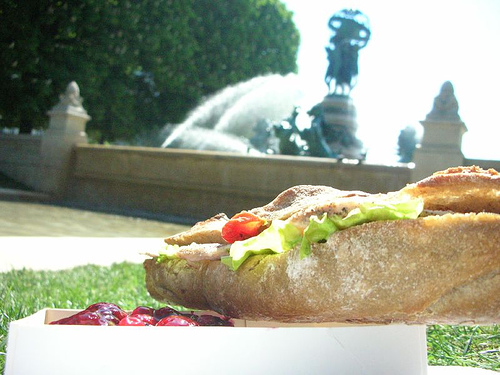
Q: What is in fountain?
A: Water.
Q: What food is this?
A: Sandwich.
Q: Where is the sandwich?
A: On a white box.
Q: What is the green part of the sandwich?
A: Lettuce.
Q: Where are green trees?
A: Behind the fountain.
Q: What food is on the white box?
A: A sandwich.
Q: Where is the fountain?
A: Behind the stone wall.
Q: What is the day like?
A: Bright and sunny.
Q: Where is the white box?
A: On the grass.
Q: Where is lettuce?
A: In the sandwich.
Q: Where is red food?
A: In the box.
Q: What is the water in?
A: Fountain.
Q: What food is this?
A: Sandwich.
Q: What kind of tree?
A: Large.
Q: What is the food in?
A: Box.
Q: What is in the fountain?
A: Water.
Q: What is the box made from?
A: Cardboard.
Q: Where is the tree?
A: Near the water.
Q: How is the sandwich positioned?
A: On the grass.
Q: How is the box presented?
A: Open.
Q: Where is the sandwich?
A: In front of an ornate park fountain.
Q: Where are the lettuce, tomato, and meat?
A: In crusty long bread.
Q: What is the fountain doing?
A: Spraying water.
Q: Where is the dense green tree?
A: In the back of curved water.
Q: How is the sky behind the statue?
A: Bright.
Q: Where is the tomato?
A: On the sandwich.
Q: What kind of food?
A: Sandwich.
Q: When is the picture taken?
A: Day time.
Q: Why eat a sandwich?
A: Hungry.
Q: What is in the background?
A: Fountain.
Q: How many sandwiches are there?
A: One.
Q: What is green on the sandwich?
A: Lettuce.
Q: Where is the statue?
A: Background.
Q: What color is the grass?
A: Green.